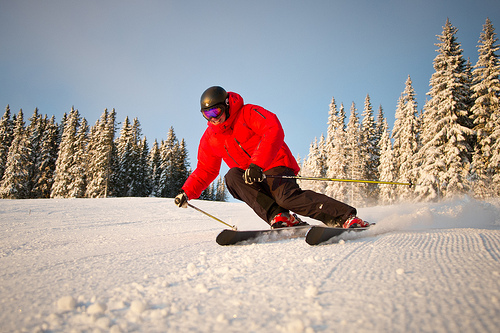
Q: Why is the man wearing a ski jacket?
A: To keep warm.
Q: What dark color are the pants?
A: Brown.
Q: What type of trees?
A: Pine.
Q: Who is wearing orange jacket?
A: Skier.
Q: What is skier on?
A: Snow.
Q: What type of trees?
A: Evergreen.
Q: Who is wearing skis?
A: Skier.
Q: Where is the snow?
A: On trees.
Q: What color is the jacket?
A: Red.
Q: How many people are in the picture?
A: One.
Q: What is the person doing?
A: Skiing.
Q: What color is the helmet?
A: Black.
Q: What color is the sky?
A: Blue.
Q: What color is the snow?
A: White.